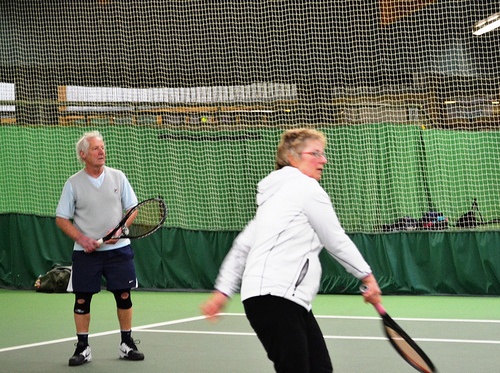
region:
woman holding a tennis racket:
[195, 123, 442, 371]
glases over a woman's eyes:
[290, 143, 328, 158]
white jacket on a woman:
[211, 165, 376, 316]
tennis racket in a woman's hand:
[357, 275, 439, 372]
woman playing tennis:
[197, 123, 441, 371]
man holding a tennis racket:
[50, 128, 171, 366]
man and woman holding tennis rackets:
[51, 123, 441, 371]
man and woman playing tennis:
[51, 126, 442, 371]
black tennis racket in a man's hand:
[81, 196, 171, 253]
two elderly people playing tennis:
[51, 126, 439, 371]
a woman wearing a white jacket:
[203, 131, 440, 371]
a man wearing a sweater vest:
[196, 130, 435, 371]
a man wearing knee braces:
[53, 130, 172, 362]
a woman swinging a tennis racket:
[196, 128, 443, 372]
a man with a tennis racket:
[50, 129, 170, 359]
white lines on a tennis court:
[0, 304, 499, 359]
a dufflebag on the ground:
[30, 261, 74, 291]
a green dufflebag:
[35, 263, 70, 293]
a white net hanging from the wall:
[1, 126, 498, 235]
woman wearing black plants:
[199, 127, 432, 372]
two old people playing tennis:
[46, 105, 441, 370]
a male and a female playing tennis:
[48, 100, 429, 371]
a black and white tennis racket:
[78, 195, 172, 258]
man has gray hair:
[59, 123, 129, 199]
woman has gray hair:
[243, 112, 357, 232]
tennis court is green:
[9, 285, 497, 370]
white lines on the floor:
[46, 123, 158, 368]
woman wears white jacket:
[196, 126, 396, 365]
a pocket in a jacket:
[285, 246, 317, 297]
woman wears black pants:
[203, 120, 393, 371]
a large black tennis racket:
[370, 285, 437, 371]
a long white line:
[327, 328, 498, 352]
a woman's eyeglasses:
[299, 148, 326, 159]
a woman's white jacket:
[214, 158, 370, 310]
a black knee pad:
[110, 285, 137, 306]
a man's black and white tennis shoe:
[117, 338, 147, 362]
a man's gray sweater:
[67, 162, 128, 248]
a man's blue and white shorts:
[68, 250, 143, 292]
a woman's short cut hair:
[269, 124, 326, 171]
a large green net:
[0, 0, 498, 297]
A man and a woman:
[41, 111, 432, 371]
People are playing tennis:
[41, 116, 382, 367]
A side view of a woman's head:
[265, 122, 332, 189]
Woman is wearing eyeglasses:
[288, 140, 338, 164]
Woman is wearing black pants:
[242, 290, 345, 372]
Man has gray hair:
[63, 121, 121, 173]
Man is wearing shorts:
[54, 242, 150, 301]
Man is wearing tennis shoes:
[48, 323, 164, 366]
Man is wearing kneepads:
[65, 285, 136, 315]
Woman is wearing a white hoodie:
[206, 161, 376, 316]